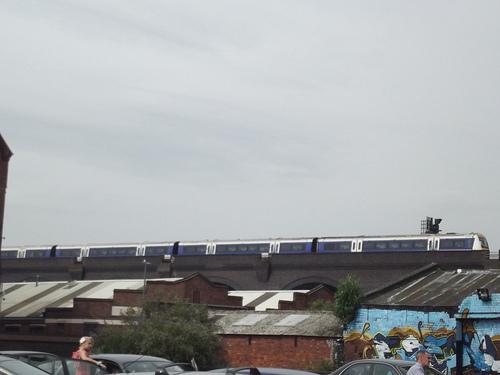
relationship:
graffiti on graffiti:
[343, 296, 500, 374] [343, 296, 500, 374]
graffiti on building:
[352, 312, 496, 356] [344, 261, 499, 366]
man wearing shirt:
[405, 347, 428, 374] [407, 361, 424, 373]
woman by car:
[68, 331, 102, 367] [40, 354, 184, 373]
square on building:
[232, 309, 267, 331] [0, 214, 497, 372]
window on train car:
[410, 239, 424, 252] [339, 225, 428, 255]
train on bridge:
[0, 233, 494, 279] [5, 257, 496, 288]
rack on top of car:
[154, 361, 262, 373] [172, 361, 326, 373]